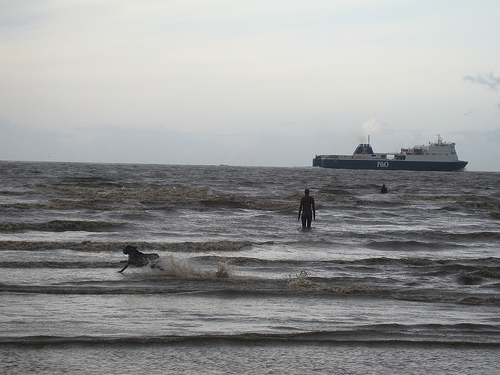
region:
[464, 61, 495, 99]
cloud in the sky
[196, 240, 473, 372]
waves on the beach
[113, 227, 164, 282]
dog in the waves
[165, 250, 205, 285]
water in the air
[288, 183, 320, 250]
person in the water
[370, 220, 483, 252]
waves in the water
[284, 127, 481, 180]
ship in the sea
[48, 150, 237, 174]
water on the horizon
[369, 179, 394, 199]
person in deep water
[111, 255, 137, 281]
dog's leg's running in water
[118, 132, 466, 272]
two people, a dog, and a boat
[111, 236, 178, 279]
dog running in the ocean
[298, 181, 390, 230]
two people walking in the ocean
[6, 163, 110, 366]
five small ocean waves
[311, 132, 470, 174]
large boat on the horizon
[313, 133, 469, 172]
large boat carrying freight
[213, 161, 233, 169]
boat on the horizon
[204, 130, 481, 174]
two boats on the horizon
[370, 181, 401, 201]
someone swimming toward the boat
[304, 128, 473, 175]
white and blue boat with P&O text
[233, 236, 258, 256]
Dark gray ocean water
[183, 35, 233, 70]
Small patch of an overcast sky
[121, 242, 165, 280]
Black dog running in the ocean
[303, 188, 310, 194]
Backside of person's head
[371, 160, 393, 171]
Name of ship in all white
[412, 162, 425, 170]
Dark blue part of ship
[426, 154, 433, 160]
White part of the ship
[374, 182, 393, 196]
Pedestrian in the water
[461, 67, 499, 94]
Small cloud in sky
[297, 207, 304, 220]
Left hand of person in the ocean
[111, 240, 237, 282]
dog splashing in the water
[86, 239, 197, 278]
dog running in the water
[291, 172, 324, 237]
man standing in the water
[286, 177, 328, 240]
person standing in the water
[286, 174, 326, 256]
person in a wet suit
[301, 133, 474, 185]
a ship close to the shore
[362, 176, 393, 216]
a person further from the shore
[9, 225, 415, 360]
waves splashing toward the shore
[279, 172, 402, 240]
two people in the water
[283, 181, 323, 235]
person with arms at his side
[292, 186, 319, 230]
Person walking in ocean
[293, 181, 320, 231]
person walking in water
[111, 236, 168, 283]
Dog walking in water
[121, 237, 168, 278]
Dog running in ocean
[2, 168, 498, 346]
Water is wavy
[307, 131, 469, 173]
Large boat in ocean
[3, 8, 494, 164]
Sky is overcast over ocean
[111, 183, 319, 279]
Dog and man in water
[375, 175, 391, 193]
Person in the middle of ocean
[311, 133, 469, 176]
Yacht in wavy water